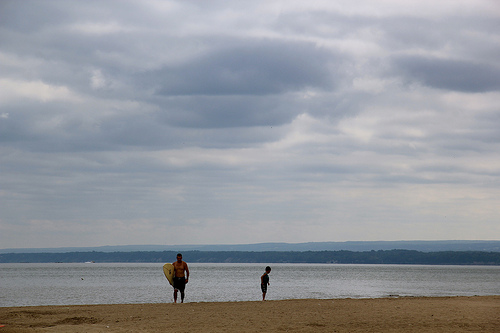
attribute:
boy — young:
[255, 263, 275, 298]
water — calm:
[322, 265, 457, 290]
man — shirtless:
[164, 250, 194, 302]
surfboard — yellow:
[153, 253, 179, 280]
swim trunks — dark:
[170, 277, 191, 292]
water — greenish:
[281, 261, 494, 296]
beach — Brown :
[0, 296, 499, 331]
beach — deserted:
[0, 273, 495, 329]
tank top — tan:
[167, 253, 191, 285]